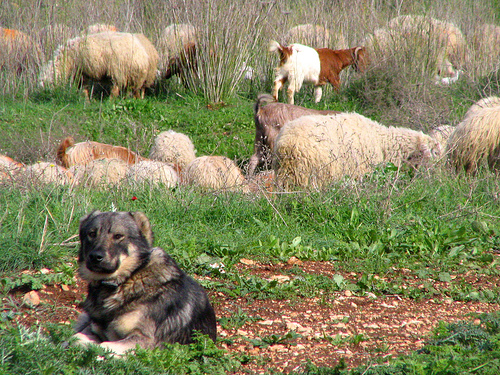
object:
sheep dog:
[60, 208, 217, 358]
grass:
[0, 179, 499, 375]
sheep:
[73, 35, 197, 109]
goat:
[265, 34, 370, 109]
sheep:
[182, 154, 243, 193]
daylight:
[346, 0, 498, 120]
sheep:
[56, 139, 183, 193]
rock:
[20, 290, 42, 309]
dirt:
[0, 258, 498, 375]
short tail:
[142, 41, 159, 88]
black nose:
[88, 248, 104, 265]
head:
[75, 207, 150, 279]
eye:
[113, 229, 123, 243]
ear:
[131, 209, 154, 242]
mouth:
[84, 262, 118, 274]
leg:
[107, 79, 123, 101]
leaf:
[343, 209, 366, 237]